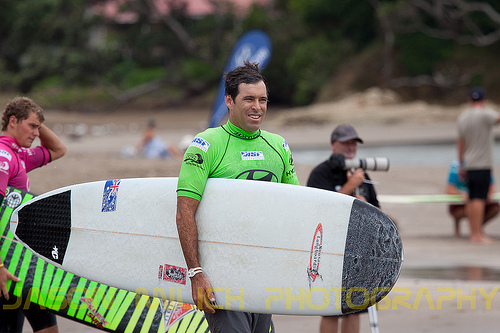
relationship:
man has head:
[176, 62, 303, 328] [224, 61, 267, 133]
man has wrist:
[176, 62, 303, 328] [185, 263, 205, 281]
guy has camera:
[305, 125, 379, 332] [332, 152, 390, 200]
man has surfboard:
[176, 62, 303, 328] [10, 178, 404, 316]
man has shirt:
[176, 62, 303, 328] [176, 122, 303, 316]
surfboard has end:
[10, 178, 404, 316] [383, 216, 404, 304]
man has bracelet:
[176, 62, 303, 328] [187, 267, 205, 278]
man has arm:
[176, 62, 303, 328] [176, 133, 215, 313]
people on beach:
[3, 60, 499, 332] [422, 286, 496, 320]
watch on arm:
[187, 267, 202, 278] [179, 217, 219, 315]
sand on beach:
[415, 279, 498, 324] [33, 116, 493, 327]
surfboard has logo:
[4, 176, 398, 331] [157, 263, 187, 286]